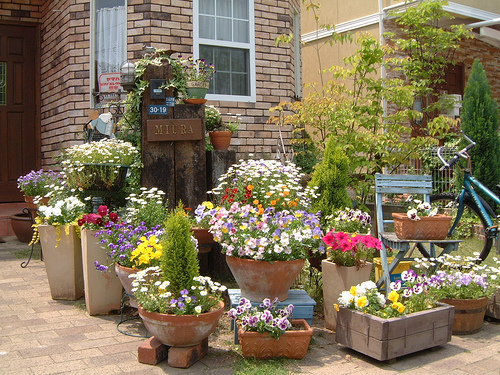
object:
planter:
[137, 294, 224, 345]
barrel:
[437, 296, 488, 335]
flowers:
[414, 252, 497, 290]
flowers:
[405, 195, 438, 221]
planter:
[391, 211, 452, 240]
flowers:
[16, 169, 66, 198]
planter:
[24, 196, 50, 224]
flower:
[372, 238, 381, 250]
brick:
[136, 337, 169, 366]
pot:
[136, 290, 224, 347]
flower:
[392, 302, 405, 312]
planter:
[335, 288, 455, 365]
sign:
[100, 73, 121, 91]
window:
[89, 1, 128, 109]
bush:
[160, 199, 200, 302]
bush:
[267, 33, 477, 220]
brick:
[136, 336, 208, 369]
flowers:
[94, 221, 166, 273]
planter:
[114, 262, 161, 308]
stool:
[226, 288, 316, 344]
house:
[1, 1, 302, 237]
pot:
[236, 318, 313, 359]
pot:
[226, 251, 307, 302]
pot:
[320, 256, 373, 332]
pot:
[391, 208, 451, 239]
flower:
[195, 306, 202, 314]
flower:
[263, 298, 271, 308]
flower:
[260, 237, 269, 246]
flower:
[340, 241, 352, 251]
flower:
[407, 208, 420, 221]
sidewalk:
[1, 245, 480, 372]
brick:
[15, 309, 59, 322]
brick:
[67, 332, 120, 352]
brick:
[23, 347, 92, 374]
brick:
[46, 321, 103, 341]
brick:
[16, 333, 78, 358]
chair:
[373, 172, 462, 299]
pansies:
[404, 195, 440, 221]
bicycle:
[413, 130, 500, 271]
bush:
[271, 0, 470, 213]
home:
[300, 0, 499, 199]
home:
[0, 0, 304, 237]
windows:
[88, 0, 256, 107]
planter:
[129, 199, 224, 347]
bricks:
[138, 335, 210, 368]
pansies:
[414, 251, 498, 299]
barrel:
[441, 296, 486, 336]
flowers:
[333, 270, 448, 313]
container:
[334, 294, 454, 361]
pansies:
[194, 200, 321, 261]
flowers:
[15, 170, 61, 195]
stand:
[0, 202, 43, 235]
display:
[140, 48, 208, 213]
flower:
[195, 59, 200, 65]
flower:
[178, 54, 183, 58]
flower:
[209, 62, 215, 68]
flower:
[199, 67, 203, 70]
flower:
[155, 48, 174, 57]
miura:
[154, 124, 195, 135]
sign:
[147, 119, 203, 142]